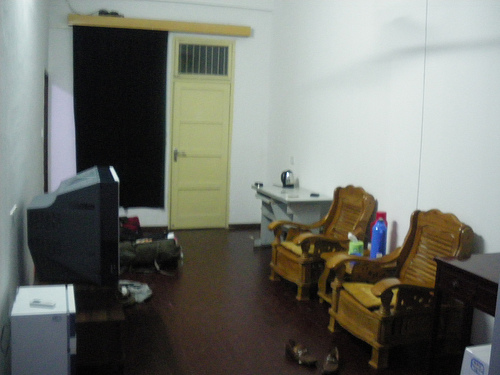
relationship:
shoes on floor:
[286, 331, 351, 365] [34, 226, 472, 374]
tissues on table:
[345, 236, 365, 256] [320, 254, 412, 269]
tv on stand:
[23, 170, 125, 303] [65, 297, 130, 366]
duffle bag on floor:
[121, 236, 181, 277] [34, 226, 472, 374]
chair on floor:
[268, 184, 377, 303] [34, 226, 472, 374]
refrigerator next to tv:
[16, 286, 75, 368] [23, 170, 125, 303]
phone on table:
[307, 193, 318, 197] [255, 181, 323, 243]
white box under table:
[458, 347, 500, 371] [434, 251, 497, 308]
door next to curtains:
[174, 78, 227, 228] [74, 28, 166, 205]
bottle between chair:
[369, 217, 386, 262] [268, 184, 377, 303]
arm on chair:
[291, 235, 341, 245] [277, 187, 368, 281]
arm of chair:
[376, 271, 427, 304] [340, 218, 461, 340]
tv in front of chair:
[23, 170, 125, 303] [268, 184, 377, 303]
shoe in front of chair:
[321, 347, 344, 373] [340, 218, 461, 340]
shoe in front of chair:
[284, 342, 315, 364] [340, 218, 461, 340]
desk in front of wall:
[255, 181, 323, 243] [273, 8, 498, 260]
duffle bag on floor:
[131, 236, 175, 262] [34, 226, 472, 374]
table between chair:
[320, 254, 412, 269] [268, 184, 377, 303]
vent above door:
[177, 41, 228, 76] [174, 78, 227, 228]